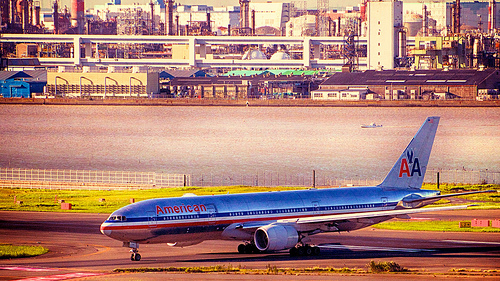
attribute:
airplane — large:
[92, 107, 500, 273]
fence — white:
[2, 168, 191, 191]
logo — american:
[399, 151, 424, 181]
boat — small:
[358, 118, 384, 130]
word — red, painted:
[153, 200, 210, 216]